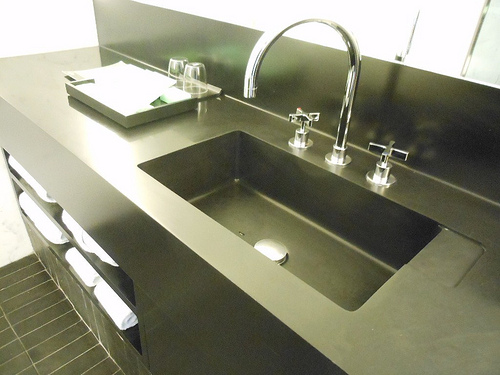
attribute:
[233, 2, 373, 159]
faucet — silver, metal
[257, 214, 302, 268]
drain — metal, silver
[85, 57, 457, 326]
sink — metal, steel, silver, rectangular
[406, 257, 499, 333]
counter — top, black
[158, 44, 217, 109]
cup — upsidedown, clear, glass, next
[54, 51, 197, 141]
tray — silver, small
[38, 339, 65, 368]
floor — tiled, tile, black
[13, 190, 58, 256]
towel — folded, white, under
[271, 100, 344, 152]
handle — silver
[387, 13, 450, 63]
mirror — behind